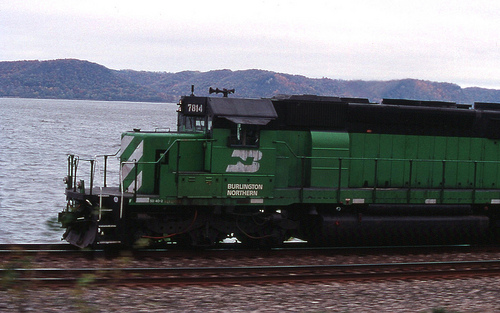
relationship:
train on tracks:
[57, 84, 498, 254] [0, 239, 498, 279]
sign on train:
[225, 148, 267, 172] [57, 84, 498, 254]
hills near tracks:
[0, 54, 499, 101] [3, 240, 498, 288]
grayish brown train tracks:
[7, 273, 494, 284] [23, 282, 490, 313]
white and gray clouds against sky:
[50, 51, 70, 56] [2, 104, 144, 140]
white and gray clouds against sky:
[9, 100, 19, 119] [64, 50, 488, 53]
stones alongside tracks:
[9, 286, 499, 311] [7, 239, 498, 309]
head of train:
[115, 125, 148, 205] [57, 84, 498, 254]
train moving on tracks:
[57, 84, 498, 254] [4, 236, 494, 290]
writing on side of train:
[221, 175, 263, 199] [57, 74, 497, 266]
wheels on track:
[128, 205, 298, 252] [0, 240, 498, 283]